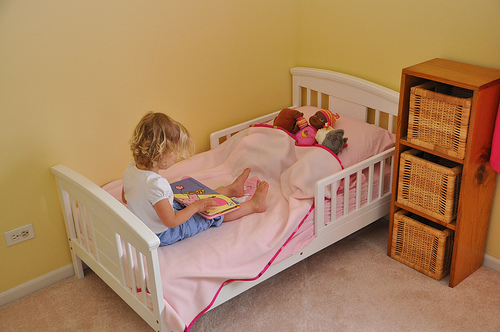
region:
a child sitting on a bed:
[117, 108, 305, 253]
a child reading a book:
[127, 101, 257, 248]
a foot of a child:
[250, 175, 271, 217]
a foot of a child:
[230, 165, 252, 198]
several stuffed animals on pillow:
[265, 102, 350, 158]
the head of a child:
[126, 107, 192, 174]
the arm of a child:
[150, 188, 212, 229]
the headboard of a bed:
[284, 59, 404, 132]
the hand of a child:
[190, 193, 215, 214]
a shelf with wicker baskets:
[385, 64, 478, 288]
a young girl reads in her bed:
[112, 90, 274, 241]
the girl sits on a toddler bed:
[36, 63, 429, 318]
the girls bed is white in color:
[32, 165, 174, 325]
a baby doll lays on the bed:
[288, 104, 338, 150]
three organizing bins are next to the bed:
[385, 54, 492, 289]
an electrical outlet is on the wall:
[6, 213, 36, 252]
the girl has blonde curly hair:
[122, 108, 190, 164]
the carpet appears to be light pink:
[269, 260, 495, 325]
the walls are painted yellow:
[21, 10, 496, 173]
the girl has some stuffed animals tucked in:
[273, 98, 344, 165]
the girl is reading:
[98, 85, 290, 232]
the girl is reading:
[57, 93, 214, 243]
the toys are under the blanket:
[243, 85, 348, 196]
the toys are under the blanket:
[226, 85, 386, 235]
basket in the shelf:
[370, 148, 453, 216]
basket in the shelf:
[381, 225, 438, 277]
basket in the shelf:
[398, 92, 463, 158]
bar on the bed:
[326, 182, 339, 220]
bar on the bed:
[335, 173, 352, 212]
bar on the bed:
[367, 165, 374, 206]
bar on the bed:
[374, 164, 386, 195]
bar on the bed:
[368, 112, 384, 128]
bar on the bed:
[140, 250, 153, 303]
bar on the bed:
[126, 246, 139, 296]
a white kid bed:
[40, 34, 414, 327]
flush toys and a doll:
[269, 102, 347, 163]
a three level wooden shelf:
[387, 49, 498, 292]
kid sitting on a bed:
[112, 104, 274, 242]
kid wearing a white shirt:
[112, 96, 274, 248]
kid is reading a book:
[114, 110, 273, 252]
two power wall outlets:
[2, 217, 38, 250]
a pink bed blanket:
[99, 119, 351, 330]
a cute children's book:
[162, 172, 242, 217]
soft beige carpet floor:
[292, 262, 387, 329]